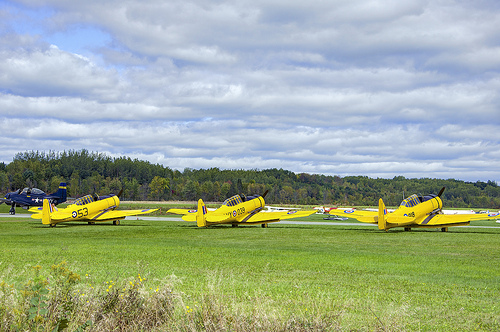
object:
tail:
[167, 198, 229, 227]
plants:
[0, 268, 182, 332]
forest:
[0, 146, 202, 200]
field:
[0, 200, 500, 332]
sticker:
[344, 209, 354, 213]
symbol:
[202, 204, 208, 214]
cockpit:
[223, 193, 257, 206]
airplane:
[0, 182, 67, 215]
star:
[34, 197, 40, 203]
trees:
[288, 175, 379, 205]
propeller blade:
[437, 186, 445, 197]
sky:
[0, 0, 499, 166]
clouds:
[0, 0, 500, 147]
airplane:
[312, 186, 500, 232]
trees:
[447, 180, 496, 207]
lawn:
[12, 219, 485, 290]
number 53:
[77, 208, 89, 218]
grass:
[6, 228, 495, 331]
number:
[225, 208, 246, 219]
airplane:
[26, 193, 157, 228]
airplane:
[166, 190, 317, 228]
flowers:
[34, 261, 78, 273]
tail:
[354, 198, 415, 232]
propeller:
[262, 190, 269, 197]